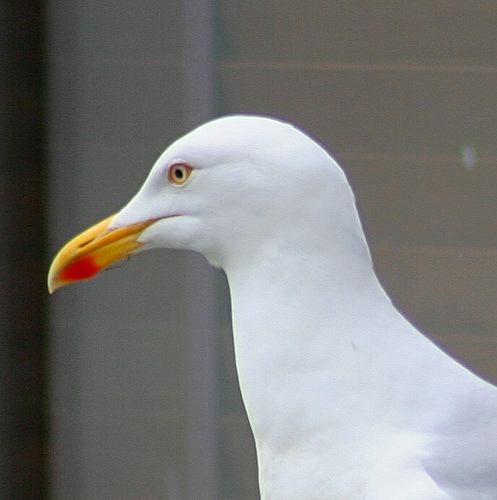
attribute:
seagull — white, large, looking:
[41, 112, 493, 500]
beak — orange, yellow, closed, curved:
[50, 233, 118, 288]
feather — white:
[387, 458, 397, 471]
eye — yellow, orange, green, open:
[165, 159, 201, 186]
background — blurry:
[8, 10, 474, 185]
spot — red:
[58, 264, 97, 282]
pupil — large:
[178, 171, 181, 174]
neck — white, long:
[232, 249, 364, 302]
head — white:
[170, 118, 351, 248]